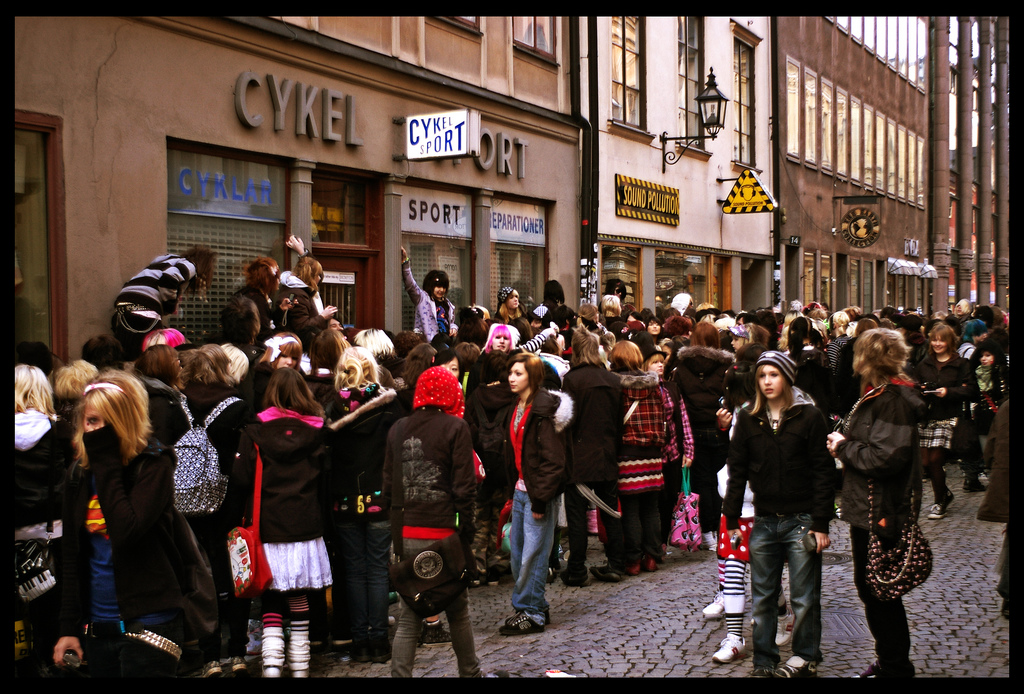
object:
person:
[230, 366, 337, 679]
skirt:
[263, 537, 333, 591]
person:
[716, 351, 832, 679]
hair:
[73, 368, 154, 469]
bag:
[227, 444, 273, 598]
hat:
[756, 351, 799, 387]